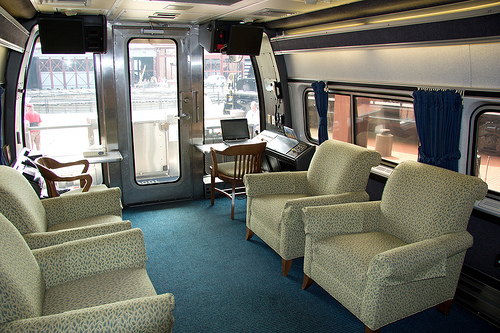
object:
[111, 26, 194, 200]
door is silver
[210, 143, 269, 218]
chair is wooden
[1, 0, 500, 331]
room has chair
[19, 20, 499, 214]
windows look out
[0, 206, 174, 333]
chair has pattern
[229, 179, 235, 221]
leg is wooden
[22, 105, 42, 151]
person outside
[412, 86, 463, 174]
curtain is hanging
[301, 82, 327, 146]
window has curtain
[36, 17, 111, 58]
tv is hanging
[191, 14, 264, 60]
tv is on ceiling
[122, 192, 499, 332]
carpet is blue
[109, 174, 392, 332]
chair has arm rest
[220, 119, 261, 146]
laptop is open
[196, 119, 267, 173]
desk has laptop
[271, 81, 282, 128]
telephone is on wall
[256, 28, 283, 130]
wall has telephone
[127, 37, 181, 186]
window is on door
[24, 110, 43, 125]
shirt is red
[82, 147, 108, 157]
box is on desk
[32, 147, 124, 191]
desk is by chair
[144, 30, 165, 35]
tube is pneumatic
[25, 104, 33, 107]
hat is red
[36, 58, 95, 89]
fence is accordeon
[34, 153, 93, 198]
chair is brown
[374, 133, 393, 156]
can is trash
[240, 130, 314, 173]
consol is near chair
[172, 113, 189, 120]
door has handle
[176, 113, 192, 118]
door is handled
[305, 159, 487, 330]
chair is on floor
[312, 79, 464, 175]
curtains are blue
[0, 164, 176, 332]
there are two chairs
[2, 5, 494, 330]
bus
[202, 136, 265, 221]
chair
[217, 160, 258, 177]
pillow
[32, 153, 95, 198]
chair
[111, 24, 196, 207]
door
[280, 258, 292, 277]
chair leg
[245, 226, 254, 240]
chair leg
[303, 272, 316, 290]
chair leg